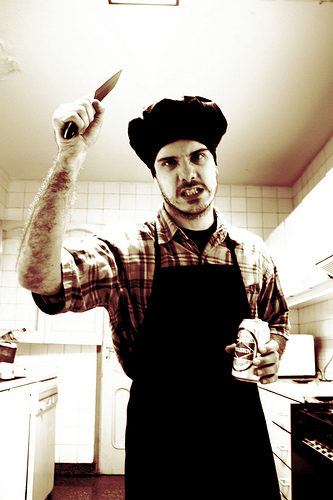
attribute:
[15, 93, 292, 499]
man — drunk, angry, scowling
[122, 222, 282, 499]
apron — black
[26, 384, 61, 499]
dishwasher — white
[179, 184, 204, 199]
mouth — open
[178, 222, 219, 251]
t-shirt — black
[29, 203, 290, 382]
shirt — plaid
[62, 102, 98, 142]
handle — black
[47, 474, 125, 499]
floor — red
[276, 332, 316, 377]
microwave — white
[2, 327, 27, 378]
bottle — clear, plastic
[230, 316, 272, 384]
beer can — aluminum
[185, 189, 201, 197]
teeth — clenched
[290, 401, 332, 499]
stove — black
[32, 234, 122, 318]
sleeve — short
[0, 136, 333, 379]
tiles — square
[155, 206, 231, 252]
collar — open